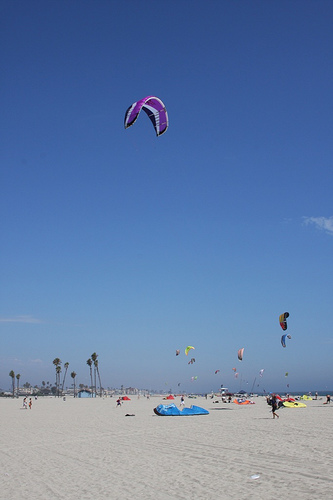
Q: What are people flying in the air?
A: Kites.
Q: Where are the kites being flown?
A: On a beach.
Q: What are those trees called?
A: Palm trees.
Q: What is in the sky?
A: Parasails.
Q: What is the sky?
A: Kites.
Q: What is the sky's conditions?
A: Clear.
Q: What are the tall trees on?
A: Beach.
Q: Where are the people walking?
A: On the beach.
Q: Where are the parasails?
A: In the sky.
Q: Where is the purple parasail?
A: In the sky.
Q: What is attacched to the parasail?
A: Rope.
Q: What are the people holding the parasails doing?
A: Parasailing.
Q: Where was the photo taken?
A: At the beach.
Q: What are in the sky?
A: Kites.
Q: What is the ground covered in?
A: Sand.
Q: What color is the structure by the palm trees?
A: Blue.